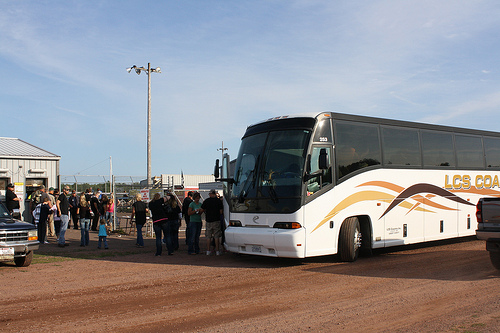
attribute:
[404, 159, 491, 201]
lettering — tan, bold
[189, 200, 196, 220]
shirt — green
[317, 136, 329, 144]
white number — small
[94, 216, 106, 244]
girl — young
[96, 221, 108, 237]
shirt — blue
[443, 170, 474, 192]
lcs — bold, tan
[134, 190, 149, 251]
woman — blonde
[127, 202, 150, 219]
shirt — black